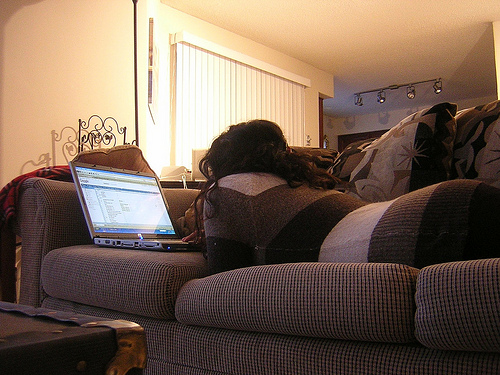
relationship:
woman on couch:
[178, 117, 500, 272] [35, 121, 483, 361]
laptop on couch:
[67, 140, 198, 260] [35, 121, 483, 361]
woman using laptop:
[178, 117, 500, 272] [67, 140, 198, 260]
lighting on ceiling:
[351, 75, 447, 107] [160, 0, 499, 120]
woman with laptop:
[178, 117, 500, 272] [63, 157, 193, 253]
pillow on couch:
[321, 102, 456, 199] [13, 164, 498, 371]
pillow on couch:
[321, 102, 456, 199] [21, 133, 499, 362]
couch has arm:
[28, 108, 498, 363] [194, 193, 248, 276]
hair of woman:
[192, 118, 353, 261] [184, 124, 499, 261]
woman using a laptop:
[178, 117, 500, 272] [68, 159, 201, 252]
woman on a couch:
[163, 130, 495, 272] [13, 164, 498, 371]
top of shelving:
[75, 115, 126, 153] [66, 112, 129, 145]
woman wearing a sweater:
[178, 117, 500, 272] [207, 180, 477, 257]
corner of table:
[68, 305, 149, 373] [0, 294, 165, 374]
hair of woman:
[198, 118, 341, 213] [185, 117, 442, 281]